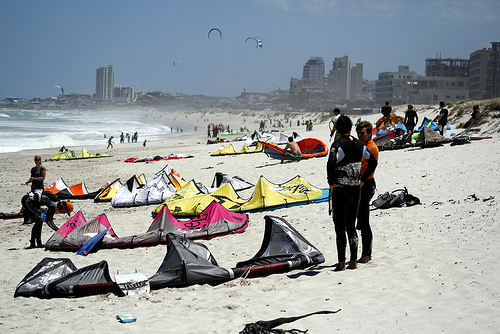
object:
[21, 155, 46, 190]
people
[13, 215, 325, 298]
kite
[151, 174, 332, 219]
kite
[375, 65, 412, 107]
buildings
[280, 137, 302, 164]
people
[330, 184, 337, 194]
hands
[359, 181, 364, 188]
hands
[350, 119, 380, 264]
person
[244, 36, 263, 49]
white kite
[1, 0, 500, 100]
blue sky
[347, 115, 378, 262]
person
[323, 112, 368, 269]
person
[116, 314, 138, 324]
object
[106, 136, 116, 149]
people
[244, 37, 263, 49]
kite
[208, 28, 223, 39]
kite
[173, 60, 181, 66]
kite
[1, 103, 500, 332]
beach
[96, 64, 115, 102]
building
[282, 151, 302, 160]
shorts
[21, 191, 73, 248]
man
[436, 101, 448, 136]
people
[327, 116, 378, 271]
people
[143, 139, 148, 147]
people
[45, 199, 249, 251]
kite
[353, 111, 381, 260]
person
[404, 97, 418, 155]
person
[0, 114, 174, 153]
ocean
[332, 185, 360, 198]
hips